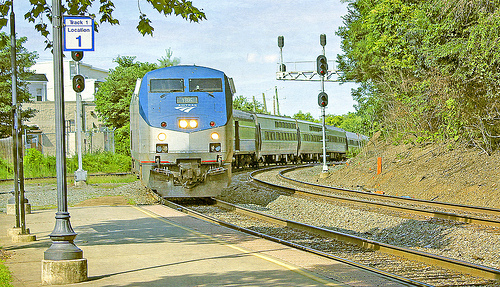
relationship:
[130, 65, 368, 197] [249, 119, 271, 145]
car appear green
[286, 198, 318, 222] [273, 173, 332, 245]
gravel between tracks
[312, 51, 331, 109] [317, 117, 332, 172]
railroad signals are on pole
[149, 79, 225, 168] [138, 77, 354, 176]
front of train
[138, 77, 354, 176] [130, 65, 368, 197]
train has a car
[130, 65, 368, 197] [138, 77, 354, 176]
car of train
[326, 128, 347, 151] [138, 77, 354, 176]
car of train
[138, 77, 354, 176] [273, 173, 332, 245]
train on tracks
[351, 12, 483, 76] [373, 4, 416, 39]
tree with leaves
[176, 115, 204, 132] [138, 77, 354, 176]
lights on train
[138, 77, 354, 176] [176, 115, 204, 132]
train has lights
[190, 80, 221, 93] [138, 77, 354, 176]
window on front of train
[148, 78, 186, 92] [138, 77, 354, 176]
window on front of train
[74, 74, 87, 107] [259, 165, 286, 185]
stop light on side of track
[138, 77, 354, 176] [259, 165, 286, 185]
train on railroad tracks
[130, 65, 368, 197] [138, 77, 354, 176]
car of a train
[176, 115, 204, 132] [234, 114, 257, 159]
lights of a passenger train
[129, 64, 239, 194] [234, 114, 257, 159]
locomotive pulling passenger train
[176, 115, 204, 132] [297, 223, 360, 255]
lights at railroad crossing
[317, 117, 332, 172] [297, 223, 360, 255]
pole at a railroad crossing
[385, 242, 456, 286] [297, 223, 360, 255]
railroad tracks at railroad crossing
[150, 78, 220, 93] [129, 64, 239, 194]
window of a locomotive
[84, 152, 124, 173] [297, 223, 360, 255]
bushes beside railroad crossing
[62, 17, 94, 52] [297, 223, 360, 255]
sign at railroad crossing